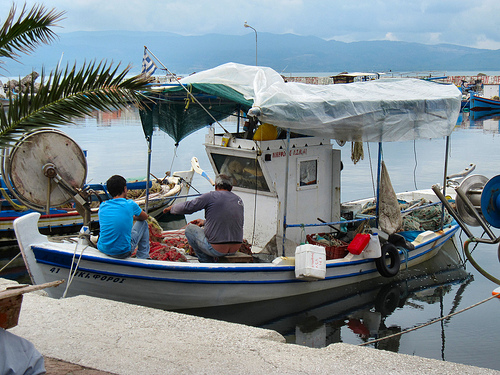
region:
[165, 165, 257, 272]
This is a person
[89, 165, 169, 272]
This is a person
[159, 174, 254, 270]
This is a person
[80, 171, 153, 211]
Head of a person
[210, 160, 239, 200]
Head of a person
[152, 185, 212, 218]
Hand of a person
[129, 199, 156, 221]
Hand of a person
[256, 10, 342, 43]
clouds covering the mountain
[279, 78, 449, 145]
white cover over boat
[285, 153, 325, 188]
small window in the boat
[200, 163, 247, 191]
man wearing white cap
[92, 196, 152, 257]
small sleeve blue shirt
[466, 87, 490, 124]
blue and white boat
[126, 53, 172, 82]
small blue and white flag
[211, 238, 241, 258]
man's crack on boat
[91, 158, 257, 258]
men sitting on the boat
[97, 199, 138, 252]
The light blue shirt the man is wearing.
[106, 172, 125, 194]
The black hair of the man in the light blue shirt.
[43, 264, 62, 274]
The number 41 on the boat.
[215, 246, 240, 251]
The man's bare skin.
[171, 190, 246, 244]
The long sleeve shirt of the man.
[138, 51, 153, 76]
The blue and white flag.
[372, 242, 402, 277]
The small tire on the side of the boat.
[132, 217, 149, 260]
The jeans the man on the left is wearing.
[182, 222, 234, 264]
The jeans the man on the right is wearing.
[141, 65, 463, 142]
The canopy of the boat.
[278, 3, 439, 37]
Section of the sky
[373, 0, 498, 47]
Section of the sky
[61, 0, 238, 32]
Section of the sky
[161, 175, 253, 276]
This is a person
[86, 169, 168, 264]
This is a person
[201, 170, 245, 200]
Head of a person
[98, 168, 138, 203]
Head of a person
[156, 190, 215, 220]
Hand of a person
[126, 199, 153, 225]
Hand of a person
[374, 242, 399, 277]
The tire on the side of the boat.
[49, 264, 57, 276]
The number 4 on the side of the boat.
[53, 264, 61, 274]
The number 1 on the side of the boat.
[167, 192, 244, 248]
The long sleeve shirt the man is wearing.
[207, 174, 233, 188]
The hat the man is wearing.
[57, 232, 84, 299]
The rope to the left of the man in the blue shirt.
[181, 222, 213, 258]
The jeans the man sitting on the right is wearing.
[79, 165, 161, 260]
this is a person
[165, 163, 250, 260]
this is a person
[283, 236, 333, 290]
this is a Jerry can